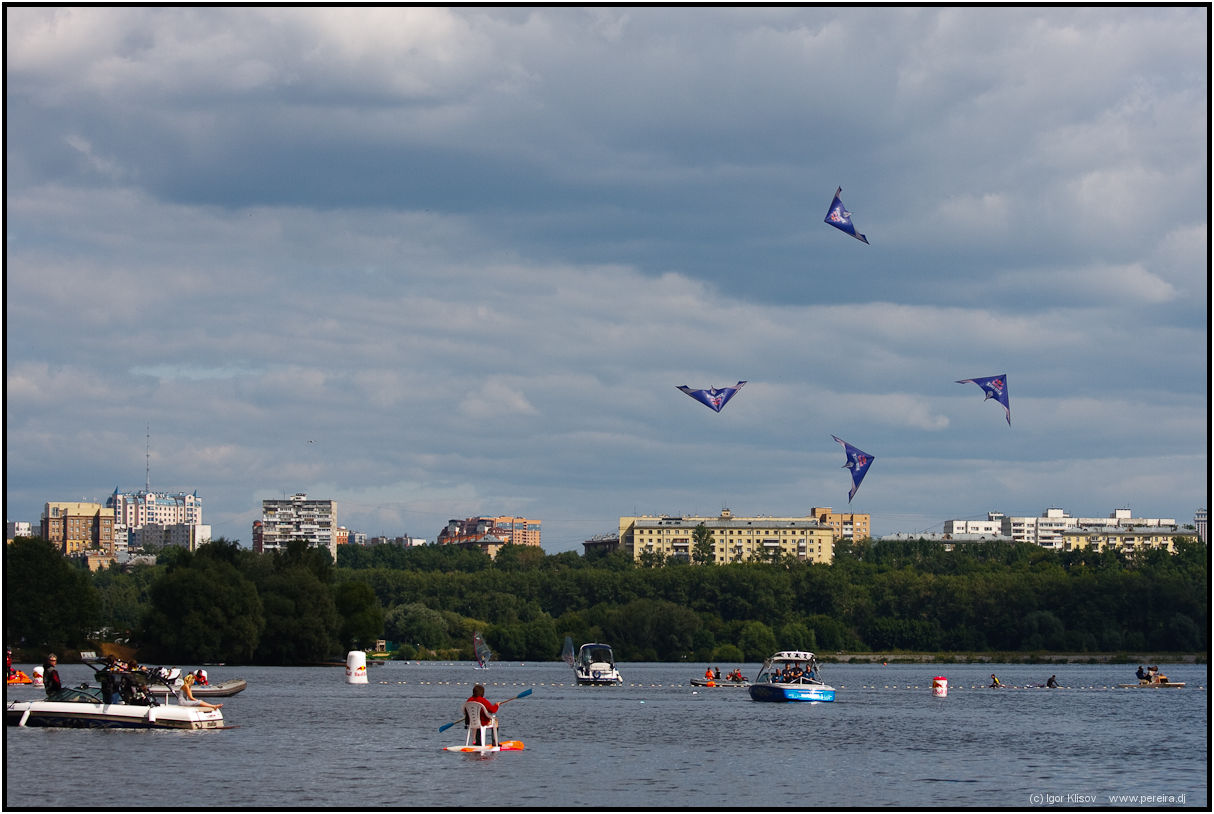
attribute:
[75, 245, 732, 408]
clouds — white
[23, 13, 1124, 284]
clouds — white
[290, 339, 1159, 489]
clouds — white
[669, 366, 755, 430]
kite — purple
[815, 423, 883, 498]
kite — purple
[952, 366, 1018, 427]
kite — purple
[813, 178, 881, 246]
kite — purple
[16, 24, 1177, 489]
sky — overcast, cloudy, blue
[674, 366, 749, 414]
kite — purple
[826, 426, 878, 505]
kite — purple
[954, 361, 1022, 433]
kite — purple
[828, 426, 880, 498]
kite — purple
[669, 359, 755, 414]
kite — purple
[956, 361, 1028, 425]
kite — purple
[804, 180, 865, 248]
kite — purple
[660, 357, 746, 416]
kite — purple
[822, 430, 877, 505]
kite — purple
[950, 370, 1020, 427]
kite — purple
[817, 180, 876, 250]
kite — purple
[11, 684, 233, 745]
motorboat — white, black, motor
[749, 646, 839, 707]
motorboat — motor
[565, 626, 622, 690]
motorboat — motor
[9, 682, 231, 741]
boat — black, white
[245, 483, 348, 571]
building — tall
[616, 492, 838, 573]
building — tall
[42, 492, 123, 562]
building — tall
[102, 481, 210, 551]
building — tall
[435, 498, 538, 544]
building — tall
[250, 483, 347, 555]
building — tall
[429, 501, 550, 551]
building — tall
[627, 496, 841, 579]
building — tall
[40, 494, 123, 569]
building — tall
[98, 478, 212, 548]
building — tall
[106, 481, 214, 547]
building — white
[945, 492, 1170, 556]
building — white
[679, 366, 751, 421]
kite — being flown in the air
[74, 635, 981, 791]
people — enjoying the outdoors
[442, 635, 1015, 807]
people — enjoying the outdoors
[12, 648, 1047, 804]
people — enjoying the outdoors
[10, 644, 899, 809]
people — enjoying the outdoors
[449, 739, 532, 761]
float — orange and white,  person's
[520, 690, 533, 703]
oar —  blue,  paddle's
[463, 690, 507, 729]
shirt —  red,  person's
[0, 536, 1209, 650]
trees —  green,  lush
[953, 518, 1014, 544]
building — w/ wall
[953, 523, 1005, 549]
building — w/ wall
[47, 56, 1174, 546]
sky — blue 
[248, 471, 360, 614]
apartment — white 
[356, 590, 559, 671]
bushes — green 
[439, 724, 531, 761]
boat — orange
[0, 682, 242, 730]
barge — white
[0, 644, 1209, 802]
water — blue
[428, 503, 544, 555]
building — brown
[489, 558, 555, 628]
leaves — green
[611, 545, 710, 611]
leaves — green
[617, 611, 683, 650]
leaves — green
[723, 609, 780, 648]
leaves — green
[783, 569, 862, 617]
leaves — green